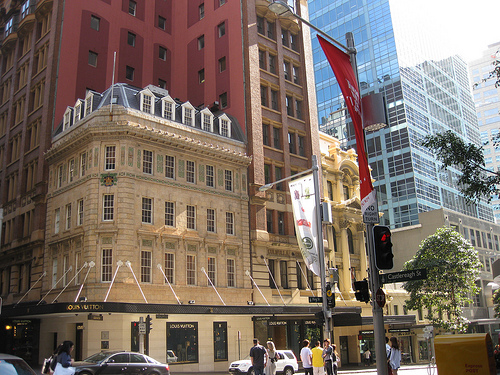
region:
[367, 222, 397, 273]
traffic light with red light on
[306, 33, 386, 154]
the banner is red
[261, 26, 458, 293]
the banner is red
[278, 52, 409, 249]
the banner is red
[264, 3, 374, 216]
the banner is red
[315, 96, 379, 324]
the banner is red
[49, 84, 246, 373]
a shorter building among the skyscrapers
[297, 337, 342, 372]
people standing around the sidewalk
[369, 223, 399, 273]
the traffic lights with ther ed light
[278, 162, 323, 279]
a banner hanging on the pole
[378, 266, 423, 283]
the street sign hanging on the pole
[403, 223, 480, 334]
the tree sitting in front of the building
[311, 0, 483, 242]
a tall building iwth a lot of glass on it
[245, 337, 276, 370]
people getting ready to cross the street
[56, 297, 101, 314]
the sign put on the awning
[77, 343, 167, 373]
a car sitting on the road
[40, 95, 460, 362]
this is a picture of a city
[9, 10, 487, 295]
lots of buildings are in the shot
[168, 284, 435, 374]
people on the street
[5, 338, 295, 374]
cars driving on the street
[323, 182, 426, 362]
a street light to direct traffic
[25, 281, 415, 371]
businesses along the street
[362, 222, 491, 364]
a tree by the building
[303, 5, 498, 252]
a glass covered buildiing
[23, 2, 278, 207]
the top part of this building is maroon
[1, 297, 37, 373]
a light is on this building